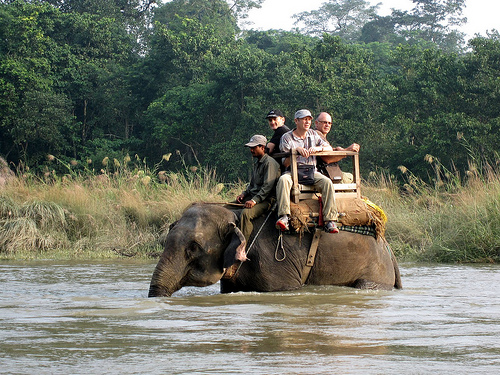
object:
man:
[275, 109, 340, 238]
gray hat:
[294, 109, 313, 120]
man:
[223, 134, 281, 251]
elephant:
[146, 198, 402, 298]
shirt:
[240, 153, 280, 204]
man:
[314, 112, 354, 192]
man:
[276, 109, 338, 234]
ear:
[221, 222, 247, 269]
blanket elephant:
[288, 193, 386, 243]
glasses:
[318, 121, 333, 125]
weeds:
[18, 175, 136, 248]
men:
[228, 106, 365, 266]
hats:
[243, 108, 313, 147]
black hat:
[265, 109, 283, 119]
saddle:
[258, 147, 386, 235]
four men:
[223, 108, 355, 244]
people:
[223, 109, 354, 246]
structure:
[279, 141, 361, 205]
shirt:
[269, 124, 294, 153]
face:
[319, 115, 331, 133]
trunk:
[146, 255, 186, 297]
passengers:
[266, 108, 356, 234]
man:
[265, 109, 292, 173]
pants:
[223, 197, 271, 246]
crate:
[289, 148, 361, 206]